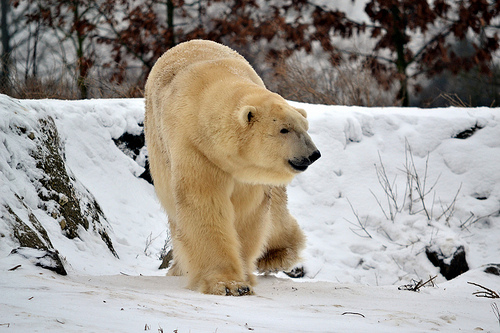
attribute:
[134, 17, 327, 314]
bear — WHITE, FUZZY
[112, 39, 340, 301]
bear — large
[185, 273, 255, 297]
foot — black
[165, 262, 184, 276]
foot — black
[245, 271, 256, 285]
foot — black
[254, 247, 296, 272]
foot — black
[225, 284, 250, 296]
claws — black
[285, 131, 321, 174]
snout — brown, black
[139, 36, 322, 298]
bear — WHITE, large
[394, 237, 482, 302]
rock — black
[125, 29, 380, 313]
polar bear — white, dirty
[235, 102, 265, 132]
ear — perky, white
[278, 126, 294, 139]
eye — small, black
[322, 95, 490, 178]
hillside — snow covered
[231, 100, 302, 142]
head — large